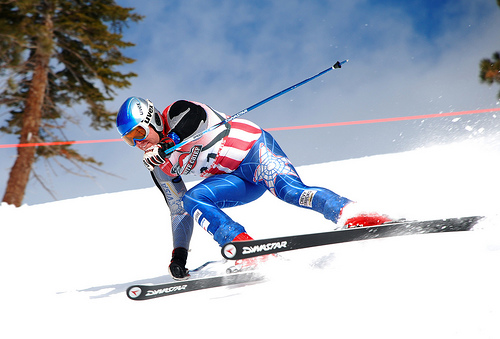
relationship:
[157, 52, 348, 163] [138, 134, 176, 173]
ski pole in hand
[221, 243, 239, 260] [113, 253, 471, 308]
design on ski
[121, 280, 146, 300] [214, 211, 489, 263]
design on ski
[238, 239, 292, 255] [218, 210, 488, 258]
print on ski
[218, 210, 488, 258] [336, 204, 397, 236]
ski on foot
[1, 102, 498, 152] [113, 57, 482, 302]
red light behind skier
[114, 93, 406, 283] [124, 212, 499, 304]
man on skis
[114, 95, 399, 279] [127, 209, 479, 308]
skier wearing black skis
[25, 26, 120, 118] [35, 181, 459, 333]
tree on mountain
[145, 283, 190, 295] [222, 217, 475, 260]
letters on black ski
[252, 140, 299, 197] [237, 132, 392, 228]
star on leg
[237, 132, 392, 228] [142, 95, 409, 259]
leg of ski suit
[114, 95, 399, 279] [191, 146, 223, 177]
skier wearing race bib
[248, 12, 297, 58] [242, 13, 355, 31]
clouds in sky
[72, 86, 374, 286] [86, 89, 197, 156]
person wearing helmet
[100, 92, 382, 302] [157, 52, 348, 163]
person holding ski pole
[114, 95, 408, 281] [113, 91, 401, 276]
person wearing suit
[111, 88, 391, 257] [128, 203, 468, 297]
man wearing skis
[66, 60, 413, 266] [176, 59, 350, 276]
man holding ski poles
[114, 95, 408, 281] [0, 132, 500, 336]
person on ice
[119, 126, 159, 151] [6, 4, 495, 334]
goggles in photo